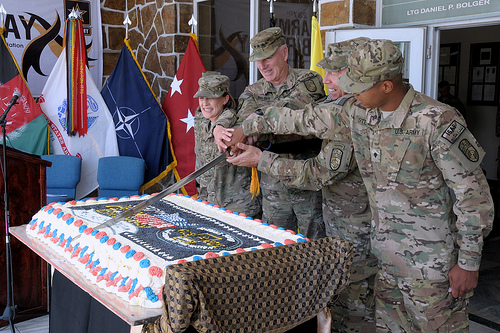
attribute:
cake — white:
[61, 199, 197, 259]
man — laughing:
[334, 73, 399, 110]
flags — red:
[27, 69, 140, 136]